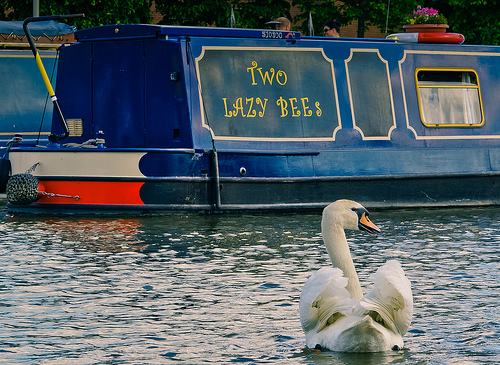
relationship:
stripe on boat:
[6, 150, 148, 181] [6, 14, 499, 212]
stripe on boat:
[39, 181, 145, 206] [6, 14, 499, 212]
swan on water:
[298, 197, 413, 353] [0, 208, 499, 364]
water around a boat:
[0, 208, 499, 364] [6, 14, 499, 212]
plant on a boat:
[402, 4, 450, 34] [6, 14, 499, 212]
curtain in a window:
[418, 81, 483, 125] [413, 68, 487, 128]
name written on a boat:
[218, 60, 324, 119] [6, 14, 499, 212]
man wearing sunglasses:
[321, 22, 343, 39] [323, 27, 336, 32]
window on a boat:
[413, 68, 487, 128] [6, 14, 499, 212]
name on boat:
[218, 60, 324, 119] [6, 14, 499, 212]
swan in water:
[298, 197, 413, 353] [0, 208, 499, 364]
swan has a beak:
[298, 197, 413, 353] [359, 214, 383, 236]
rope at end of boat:
[4, 172, 40, 207] [6, 14, 499, 212]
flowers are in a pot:
[410, 5, 439, 19] [403, 25, 451, 33]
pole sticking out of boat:
[21, 11, 87, 141] [6, 14, 499, 212]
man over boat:
[321, 22, 343, 39] [6, 14, 499, 212]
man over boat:
[265, 16, 293, 35] [6, 14, 499, 212]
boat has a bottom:
[6, 14, 499, 212] [9, 196, 500, 213]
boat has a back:
[6, 14, 499, 212] [7, 23, 197, 211]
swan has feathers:
[298, 197, 413, 353] [290, 260, 418, 352]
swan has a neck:
[298, 197, 413, 353] [320, 230, 362, 304]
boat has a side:
[6, 14, 499, 212] [178, 39, 498, 207]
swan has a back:
[298, 197, 413, 353] [340, 313, 396, 355]